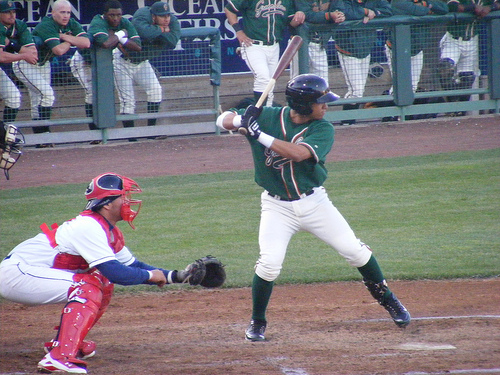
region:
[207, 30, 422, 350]
Man with green baseball uniform.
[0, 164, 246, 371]
Baseball catcher with red helmet.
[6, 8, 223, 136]
Baseball players with green uniforms in dugout.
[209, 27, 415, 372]
Baseball player swinging bat.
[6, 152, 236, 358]
Baseball catcher looking at pitcher.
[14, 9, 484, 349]
Baseball field with cut grass.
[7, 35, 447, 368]
Baseball player with black helmet.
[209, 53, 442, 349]
Baseball player with black cleets.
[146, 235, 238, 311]
Catcher's mitt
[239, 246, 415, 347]
Green socks.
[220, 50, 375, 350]
this is a baseball player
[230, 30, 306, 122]
the player is with a bat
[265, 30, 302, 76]
the bat is brown in color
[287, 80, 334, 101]
the player is wearing a helmet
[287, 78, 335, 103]
the helmet is blue in color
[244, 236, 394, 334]
the legs are apart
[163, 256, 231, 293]
the player is wearing a baseball glove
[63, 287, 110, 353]
the shin guards are red in color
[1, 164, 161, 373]
the player is squatting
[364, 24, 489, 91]
this is a grilled fence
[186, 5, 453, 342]
Baseball player is holding a bat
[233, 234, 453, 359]
Player is wearing black shoes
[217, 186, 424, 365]
Player is wearing white pants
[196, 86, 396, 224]
Player's baseball jersey is green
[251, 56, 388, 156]
Player's helmet is black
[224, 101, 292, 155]
Player is wearing black and white gloves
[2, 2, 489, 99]
Baseball players are in the background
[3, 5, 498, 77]
Players are wearing a green baseball jersey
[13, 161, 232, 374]
Player is wearing a white baseball outfit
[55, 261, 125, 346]
Baseball player's knee pads are red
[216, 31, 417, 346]
Baseball player waiting for a pitch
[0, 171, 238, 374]
Catcher waiting for a ball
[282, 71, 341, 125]
Baseball helmet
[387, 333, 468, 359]
Home plate on a baseball field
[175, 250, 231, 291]
Baseball catcher's mitt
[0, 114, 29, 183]
Baseball umpire's mask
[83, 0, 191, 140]
Baseball players waiting for their turn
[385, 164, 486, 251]
Patch of grass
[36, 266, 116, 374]
Leg protection for a baseball catcher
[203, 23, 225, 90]
Padded railing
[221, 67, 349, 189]
the player is holding a bat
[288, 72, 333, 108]
this is a helmet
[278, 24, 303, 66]
this is a bat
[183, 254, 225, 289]
this is a baseball glove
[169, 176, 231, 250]
this is the grass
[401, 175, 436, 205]
the grass is green in color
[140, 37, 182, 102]
this is a fence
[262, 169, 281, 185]
the t-shirt is green in color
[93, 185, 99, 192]
the helmet is red in color